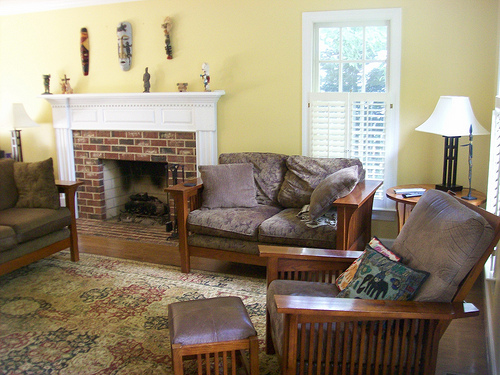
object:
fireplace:
[97, 157, 172, 229]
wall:
[0, 0, 500, 241]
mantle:
[36, 90, 225, 133]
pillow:
[332, 242, 430, 339]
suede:
[197, 161, 259, 211]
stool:
[165, 294, 260, 375]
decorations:
[115, 20, 133, 73]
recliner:
[255, 187, 500, 375]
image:
[355, 264, 396, 300]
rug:
[0, 248, 284, 375]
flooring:
[77, 233, 266, 280]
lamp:
[413, 95, 490, 193]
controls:
[392, 187, 427, 195]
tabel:
[385, 183, 487, 238]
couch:
[162, 150, 383, 275]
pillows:
[334, 235, 404, 293]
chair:
[257, 187, 500, 374]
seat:
[266, 279, 423, 368]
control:
[296, 203, 338, 229]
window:
[310, 21, 390, 200]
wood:
[125, 192, 167, 219]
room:
[0, 0, 500, 375]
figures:
[141, 66, 151, 94]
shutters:
[352, 130, 385, 135]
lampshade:
[414, 95, 492, 137]